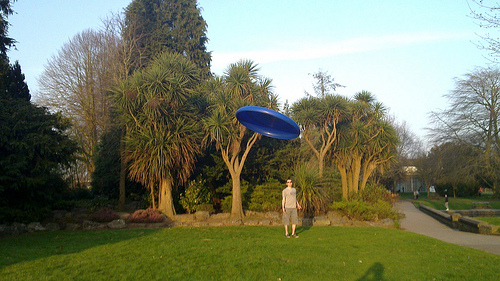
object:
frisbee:
[235, 106, 300, 139]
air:
[1, 1, 500, 280]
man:
[282, 179, 303, 238]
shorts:
[282, 208, 299, 225]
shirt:
[282, 187, 297, 209]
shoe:
[284, 233, 291, 238]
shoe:
[291, 234, 299, 238]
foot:
[285, 234, 291, 239]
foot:
[290, 234, 299, 239]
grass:
[0, 225, 500, 281]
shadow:
[354, 261, 383, 280]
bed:
[42, 222, 84, 231]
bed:
[87, 207, 119, 223]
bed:
[129, 208, 164, 223]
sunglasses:
[287, 181, 293, 183]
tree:
[109, 51, 209, 217]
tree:
[200, 59, 281, 221]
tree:
[290, 94, 348, 177]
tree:
[333, 90, 397, 197]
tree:
[286, 161, 329, 216]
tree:
[31, 27, 119, 180]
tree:
[0, 0, 91, 200]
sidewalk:
[393, 199, 500, 256]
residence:
[383, 159, 427, 192]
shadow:
[0, 229, 157, 268]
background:
[0, 29, 498, 239]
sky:
[0, 0, 499, 175]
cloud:
[290, 36, 369, 55]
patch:
[0, 225, 499, 280]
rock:
[107, 219, 127, 229]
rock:
[194, 210, 209, 219]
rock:
[314, 215, 330, 226]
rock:
[210, 213, 230, 220]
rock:
[26, 222, 45, 233]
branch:
[303, 131, 319, 159]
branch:
[319, 118, 325, 154]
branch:
[324, 118, 335, 144]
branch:
[239, 132, 258, 168]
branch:
[220, 139, 237, 170]